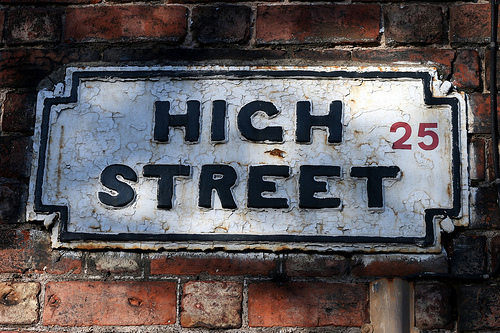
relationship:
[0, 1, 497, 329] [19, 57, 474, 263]
bricks behind placque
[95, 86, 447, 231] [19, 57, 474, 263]
writing on placque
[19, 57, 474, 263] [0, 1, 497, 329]
placque on bricks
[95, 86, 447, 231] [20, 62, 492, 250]
writing on sign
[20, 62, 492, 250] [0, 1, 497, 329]
sign on bricks